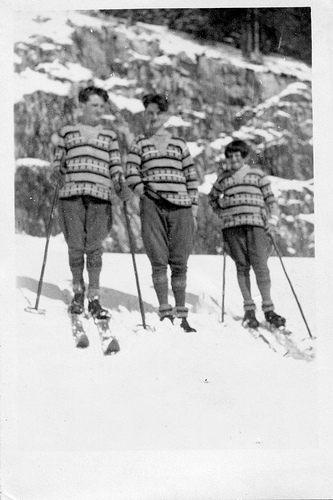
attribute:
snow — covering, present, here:
[55, 318, 326, 491]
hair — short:
[213, 129, 253, 159]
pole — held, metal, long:
[29, 171, 77, 366]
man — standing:
[124, 84, 207, 258]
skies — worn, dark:
[39, 275, 325, 372]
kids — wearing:
[41, 145, 331, 326]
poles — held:
[25, 188, 170, 406]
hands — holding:
[84, 154, 254, 237]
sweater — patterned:
[115, 130, 214, 189]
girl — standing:
[203, 86, 311, 268]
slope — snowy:
[57, 11, 319, 139]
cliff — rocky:
[119, 53, 312, 144]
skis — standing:
[25, 72, 138, 318]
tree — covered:
[214, 25, 327, 46]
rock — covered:
[21, 80, 72, 138]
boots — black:
[221, 287, 325, 338]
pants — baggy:
[126, 212, 232, 356]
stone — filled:
[177, 69, 209, 124]